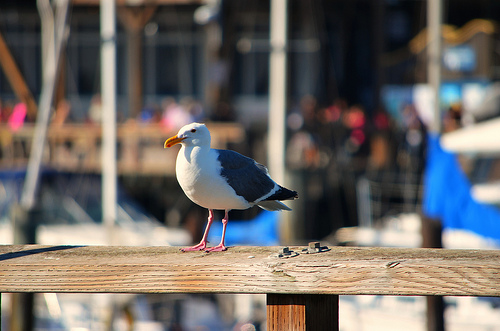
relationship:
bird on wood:
[145, 115, 307, 259] [4, 237, 499, 302]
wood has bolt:
[4, 237, 499, 302] [268, 241, 299, 261]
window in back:
[144, 39, 199, 97] [4, 6, 494, 245]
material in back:
[422, 135, 498, 240] [4, 6, 494, 245]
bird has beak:
[145, 115, 307, 259] [152, 132, 190, 151]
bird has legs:
[145, 115, 307, 259] [175, 203, 241, 254]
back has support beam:
[4, 6, 494, 245] [3, 117, 252, 176]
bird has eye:
[145, 115, 307, 259] [189, 128, 200, 136]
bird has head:
[145, 115, 307, 259] [159, 116, 214, 157]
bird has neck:
[145, 115, 307, 259] [175, 141, 212, 150]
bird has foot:
[145, 115, 307, 259] [179, 237, 210, 254]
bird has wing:
[145, 115, 307, 259] [217, 152, 302, 207]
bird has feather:
[145, 115, 307, 259] [255, 163, 272, 176]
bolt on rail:
[268, 241, 299, 261] [3, 243, 492, 326]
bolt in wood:
[268, 241, 299, 261] [4, 237, 499, 302]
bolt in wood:
[295, 236, 330, 258] [4, 237, 499, 302]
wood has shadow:
[4, 237, 499, 302] [298, 292, 341, 325]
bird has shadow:
[145, 115, 307, 259] [193, 131, 303, 229]